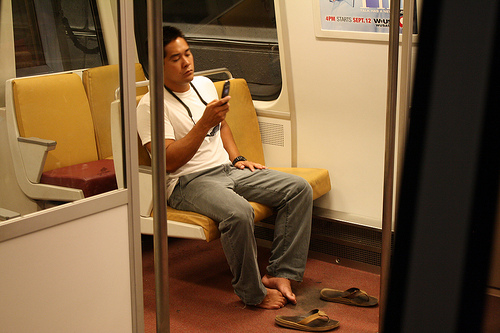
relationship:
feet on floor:
[251, 270, 302, 315] [173, 303, 288, 326]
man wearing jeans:
[135, 25, 314, 310] [165, 161, 314, 303]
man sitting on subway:
[137, 25, 347, 303] [3, 3, 497, 325]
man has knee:
[135, 25, 314, 310] [278, 174, 313, 219]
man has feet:
[135, 25, 314, 310] [221, 256, 323, 309]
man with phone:
[135, 25, 314, 310] [212, 63, 237, 109]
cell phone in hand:
[220, 80, 233, 99] [200, 95, 231, 126]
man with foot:
[135, 25, 314, 310] [226, 257, 375, 332]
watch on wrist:
[233, 154, 245, 163] [232, 154, 247, 162]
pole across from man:
[121, 44, 185, 206] [135, 36, 292, 240]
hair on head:
[162, 25, 187, 58] [162, 25, 194, 82]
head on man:
[162, 25, 194, 82] [135, 25, 314, 310]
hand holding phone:
[204, 93, 230, 128] [218, 76, 232, 101]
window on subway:
[128, 0, 286, 107] [0, 0, 498, 332]